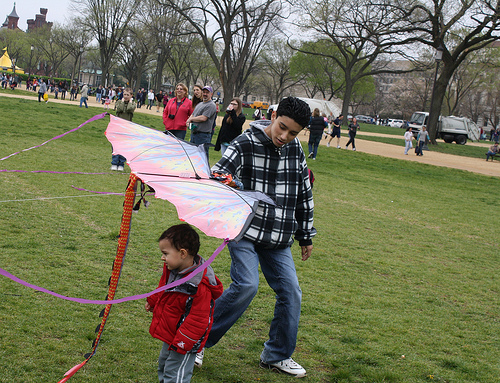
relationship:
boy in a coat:
[144, 223, 226, 383] [145, 256, 224, 356]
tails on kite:
[5, 91, 227, 331] [23, 100, 172, 237]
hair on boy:
[263, 93, 313, 150] [193, 96, 318, 381]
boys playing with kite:
[190, 95, 316, 378] [58, 110, 282, 250]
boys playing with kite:
[190, 95, 316, 378] [101, 118, 296, 277]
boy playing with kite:
[144, 223, 226, 383] [105, 114, 254, 236]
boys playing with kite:
[190, 95, 316, 378] [105, 114, 254, 236]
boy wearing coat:
[144, 223, 226, 383] [141, 257, 226, 357]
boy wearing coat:
[144, 255, 224, 352] [141, 257, 226, 357]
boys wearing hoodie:
[190, 95, 316, 378] [226, 135, 313, 238]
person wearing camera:
[159, 79, 191, 139] [166, 110, 180, 122]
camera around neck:
[166, 110, 180, 122] [175, 99, 185, 104]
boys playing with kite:
[144, 96, 316, 382] [4, 104, 279, 310]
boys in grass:
[144, 96, 316, 382] [3, 84, 498, 380]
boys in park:
[190, 95, 316, 378] [3, 2, 495, 381]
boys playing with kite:
[190, 95, 316, 378] [4, 104, 279, 310]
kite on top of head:
[4, 104, 279, 310] [154, 225, 204, 272]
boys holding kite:
[190, 95, 316, 378] [102, 110, 274, 243]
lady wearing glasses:
[214, 96, 245, 151] [228, 101, 238, 106]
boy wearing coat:
[144, 223, 226, 383] [145, 256, 224, 356]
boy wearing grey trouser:
[144, 223, 226, 383] [155, 341, 197, 381]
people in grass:
[183, 86, 217, 163] [142, 220, 222, 377]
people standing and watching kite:
[161, 79, 220, 152] [0, 111, 277, 383]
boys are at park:
[190, 95, 316, 378] [3, 2, 495, 381]